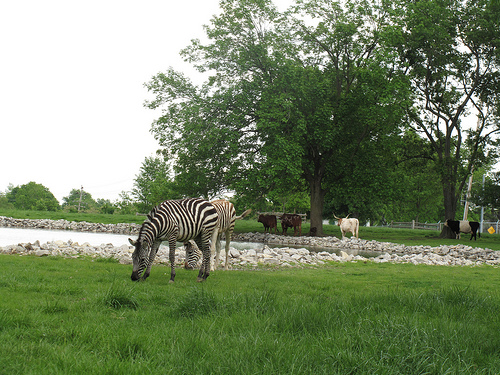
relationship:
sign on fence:
[481, 209, 496, 224] [436, 191, 497, 238]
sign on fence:
[488, 225, 497, 235] [386, 215, 496, 241]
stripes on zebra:
[168, 203, 197, 240] [126, 193, 222, 283]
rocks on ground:
[255, 247, 326, 262] [0, 210, 471, 373]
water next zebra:
[3, 228, 124, 245] [126, 198, 222, 284]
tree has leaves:
[244, 54, 416, 236] [306, 142, 333, 169]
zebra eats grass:
[126, 193, 222, 283] [93, 262, 171, 316]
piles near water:
[0, 215, 499, 267] [0, 226, 398, 258]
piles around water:
[0, 215, 499, 267] [2, 225, 477, 259]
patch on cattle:
[330, 216, 346, 230] [326, 209, 363, 241]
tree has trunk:
[244, 54, 416, 236] [301, 140, 333, 240]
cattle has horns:
[329, 200, 371, 238] [326, 203, 355, 218]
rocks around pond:
[0, 216, 498, 269] [0, 227, 427, 259]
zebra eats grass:
[126, 198, 222, 284] [1, 263, 496, 373]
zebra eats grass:
[183, 198, 250, 269] [1, 263, 496, 373]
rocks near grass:
[342, 252, 348, 266] [1, 263, 496, 373]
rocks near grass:
[294, 245, 309, 255] [1, 263, 496, 373]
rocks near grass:
[243, 250, 253, 257] [1, 263, 496, 373]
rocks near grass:
[377, 252, 385, 263] [1, 263, 496, 373]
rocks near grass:
[292, 254, 302, 259] [1, 263, 496, 373]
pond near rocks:
[0, 227, 427, 259] [32, 242, 101, 258]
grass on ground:
[101, 281, 496, 372] [406, 161, 426, 201]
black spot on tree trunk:
[309, 222, 317, 238] [308, 136, 324, 238]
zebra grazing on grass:
[183, 199, 252, 269] [1, 209, 498, 373]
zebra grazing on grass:
[126, 198, 222, 284] [1, 209, 498, 373]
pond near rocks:
[0, 227, 427, 259] [40, 241, 55, 247]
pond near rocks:
[0, 227, 427, 259] [123, 252, 130, 264]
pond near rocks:
[0, 227, 427, 259] [106, 241, 118, 248]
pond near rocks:
[0, 227, 427, 259] [69, 241, 79, 246]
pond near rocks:
[0, 227, 427, 259] [51, 249, 66, 255]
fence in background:
[378, 214, 500, 236] [0, 0, 499, 237]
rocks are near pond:
[239, 243, 324, 268] [5, 212, 115, 245]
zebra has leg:
[126, 193, 222, 283] [160, 238, 181, 286]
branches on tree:
[410, 73, 481, 195] [375, 4, 498, 243]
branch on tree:
[457, 118, 490, 196] [375, 4, 498, 243]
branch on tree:
[442, 3, 494, 129] [375, 4, 498, 243]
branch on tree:
[350, 149, 430, 192] [375, 4, 498, 243]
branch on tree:
[416, 2, 461, 142] [375, 4, 498, 243]